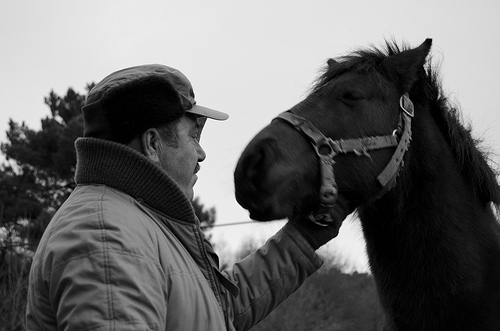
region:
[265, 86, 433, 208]
the bridle on a horse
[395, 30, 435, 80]
the horse has an ear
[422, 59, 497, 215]
the mane on a horse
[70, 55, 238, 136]
the cap is black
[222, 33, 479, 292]
the head on a horse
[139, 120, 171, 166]
the man has an ear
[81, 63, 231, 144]
a hat on head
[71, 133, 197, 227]
stand up collar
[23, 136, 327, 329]
a duct coat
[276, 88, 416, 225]
the bridle on horse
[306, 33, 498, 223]
the mane on animal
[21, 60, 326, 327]
a man standing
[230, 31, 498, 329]
a horse standing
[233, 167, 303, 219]
the mouth of horse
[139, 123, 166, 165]
the ear of man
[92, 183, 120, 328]
the stitch of coat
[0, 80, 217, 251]
a large pine tree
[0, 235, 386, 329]
a large area of bushes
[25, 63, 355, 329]
a man looking at the horse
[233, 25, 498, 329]
a horse looking at the man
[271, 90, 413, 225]
the horse's bridle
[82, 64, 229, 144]
a hat worn by the man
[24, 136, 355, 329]
a jacket worn by the man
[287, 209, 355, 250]
the man's left glove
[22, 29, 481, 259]
this photo is black and white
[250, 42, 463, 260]
the horse is black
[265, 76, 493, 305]
the horse is dark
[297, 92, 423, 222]
the horse is bridled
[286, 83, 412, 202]
the straps are gray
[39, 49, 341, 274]
this is a black and white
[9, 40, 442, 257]
this is a grayscale style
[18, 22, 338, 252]
this is monochromatic style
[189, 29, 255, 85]
the sky is cloudy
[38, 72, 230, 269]
the man has a mustache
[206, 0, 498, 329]
this is a horse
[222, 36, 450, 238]
bridle on the horse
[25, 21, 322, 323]
this is a man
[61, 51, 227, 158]
man wearing a hat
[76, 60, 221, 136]
The man is wearing a hat.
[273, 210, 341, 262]
The man is petting the horse with his hand.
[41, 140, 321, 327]
The man is wearing a heavy jacket.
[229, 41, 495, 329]
The horse is brown.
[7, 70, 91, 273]
The tall tree is behind the man.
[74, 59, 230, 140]
man wearing a hat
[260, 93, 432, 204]
black strap on the horse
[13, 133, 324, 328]
man wearing a brown jacket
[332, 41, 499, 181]
Hair on the horse head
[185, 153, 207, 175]
man with a mustache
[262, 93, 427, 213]
strap on a horse face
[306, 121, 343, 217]
strap on a horse face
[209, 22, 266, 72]
a view of sky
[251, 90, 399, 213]
a view of face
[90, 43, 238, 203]
a view of man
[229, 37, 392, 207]
a view of horse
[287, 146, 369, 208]
a view of thread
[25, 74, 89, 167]
a view of trees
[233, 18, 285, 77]
a view of clouds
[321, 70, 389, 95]
a view of fur